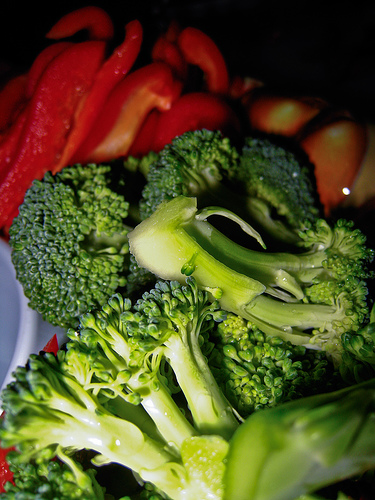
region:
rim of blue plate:
[1, 229, 66, 393]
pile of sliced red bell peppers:
[4, 9, 373, 240]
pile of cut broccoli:
[0, 114, 367, 498]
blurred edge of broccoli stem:
[222, 382, 370, 496]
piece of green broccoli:
[5, 272, 243, 497]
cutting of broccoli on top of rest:
[126, 188, 373, 361]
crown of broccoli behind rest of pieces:
[10, 151, 136, 326]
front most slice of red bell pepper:
[7, 35, 106, 237]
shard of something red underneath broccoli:
[39, 328, 64, 360]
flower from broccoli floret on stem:
[178, 250, 197, 277]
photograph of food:
[14, 14, 374, 489]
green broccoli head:
[19, 160, 143, 325]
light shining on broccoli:
[64, 310, 221, 472]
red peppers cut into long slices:
[10, 8, 169, 218]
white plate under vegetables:
[4, 220, 50, 375]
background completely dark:
[249, 13, 360, 59]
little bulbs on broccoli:
[221, 342, 257, 366]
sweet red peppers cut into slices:
[5, 3, 235, 202]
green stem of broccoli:
[151, 332, 226, 441]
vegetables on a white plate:
[7, 27, 337, 421]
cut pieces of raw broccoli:
[11, 125, 309, 370]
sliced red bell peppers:
[24, 4, 185, 133]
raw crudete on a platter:
[5, 6, 362, 293]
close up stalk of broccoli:
[224, 394, 361, 490]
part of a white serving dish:
[6, 303, 32, 353]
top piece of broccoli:
[24, 209, 70, 277]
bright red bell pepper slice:
[60, 66, 77, 90]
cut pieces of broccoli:
[71, 292, 235, 471]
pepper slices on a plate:
[48, 42, 164, 133]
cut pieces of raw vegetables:
[16, 28, 348, 334]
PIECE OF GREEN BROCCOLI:
[8, 184, 135, 311]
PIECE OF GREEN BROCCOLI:
[28, 326, 225, 482]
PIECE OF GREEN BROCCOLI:
[224, 375, 363, 482]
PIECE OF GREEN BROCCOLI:
[190, 205, 374, 308]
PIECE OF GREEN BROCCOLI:
[192, 109, 259, 174]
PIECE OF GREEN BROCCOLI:
[259, 128, 341, 205]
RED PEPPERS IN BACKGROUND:
[19, 15, 245, 162]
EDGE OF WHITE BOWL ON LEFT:
[2, 249, 41, 396]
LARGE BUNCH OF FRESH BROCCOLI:
[32, 144, 344, 498]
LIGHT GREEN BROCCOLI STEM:
[172, 346, 221, 414]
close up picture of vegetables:
[21, 164, 342, 482]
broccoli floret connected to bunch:
[8, 392, 123, 479]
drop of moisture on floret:
[106, 427, 126, 462]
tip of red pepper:
[32, 328, 51, 347]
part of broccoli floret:
[209, 331, 299, 405]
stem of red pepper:
[35, 96, 61, 142]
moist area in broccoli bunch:
[177, 438, 241, 499]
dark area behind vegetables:
[298, 61, 358, 105]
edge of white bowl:
[10, 323, 53, 353]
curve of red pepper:
[126, 78, 176, 118]